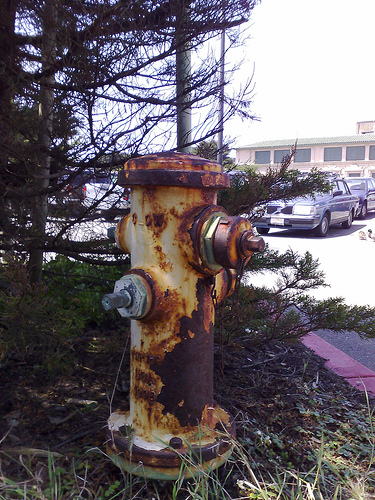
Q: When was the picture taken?
A: In the daytime.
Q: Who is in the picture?
A: No one.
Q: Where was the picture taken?
A: By a fire hydrant.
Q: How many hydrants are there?
A: 1.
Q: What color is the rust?
A: Brown.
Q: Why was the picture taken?
A: To show the hydrant.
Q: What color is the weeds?
A: Green and brown.